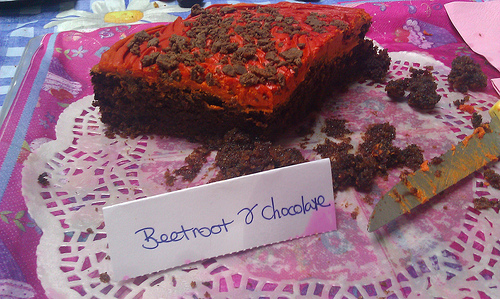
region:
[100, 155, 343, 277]
the sign is white with blue writing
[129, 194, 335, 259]
the sign says beetroot & chocolate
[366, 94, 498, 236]
a knife by the cake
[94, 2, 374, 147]
the cake is brown and red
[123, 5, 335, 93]
chunks of chocolate on the cake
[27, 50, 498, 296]
a white doily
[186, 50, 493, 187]
chunks of cake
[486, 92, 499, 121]
the knife has a yellow handle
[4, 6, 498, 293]
the tray is pink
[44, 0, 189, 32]
a white daisy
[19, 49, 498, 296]
A white doily on a plate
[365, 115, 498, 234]
A knife with orange frosting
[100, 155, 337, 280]
A white sign on the plate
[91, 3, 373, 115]
Orange frosting on a cake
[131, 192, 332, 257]
Words "Beetroot & Chocolate" on a sign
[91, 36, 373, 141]
Chocolate cake on a doily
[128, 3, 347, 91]
Bits of chocolate on frosting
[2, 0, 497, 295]
A pink and blue plate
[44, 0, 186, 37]
A daisy pattern on a tablecloth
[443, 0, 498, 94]
A pink napkin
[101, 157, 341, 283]
white label with blue inkprint on it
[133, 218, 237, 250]
blue ink print reading Beetroot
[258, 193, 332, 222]
blue ink print reading Chocolate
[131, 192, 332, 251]
blue inkprint reading Beetroot and Chocolate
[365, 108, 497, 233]
a sharp silver knife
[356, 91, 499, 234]
knife with orange frosting and cake crumbs on it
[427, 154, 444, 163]
brown cake crumb on a knife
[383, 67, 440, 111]
large chocolate cake crumb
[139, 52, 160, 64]
chocolate topping on a piece of cake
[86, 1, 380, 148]
piece of red frosted chocolate cake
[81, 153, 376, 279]
a handwritten sign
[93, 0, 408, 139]
chocolate cake with red icing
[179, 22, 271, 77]
chocolate shaving on the cake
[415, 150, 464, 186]
crumbs on a knife blade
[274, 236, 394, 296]
oil on a white doily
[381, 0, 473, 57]
colorful table cloth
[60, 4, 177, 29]
a white flower in the tablecloth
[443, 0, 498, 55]
a pink napkin on the table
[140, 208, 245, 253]
blue writing on white paper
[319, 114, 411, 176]
brown crumbs on the doily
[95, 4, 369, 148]
beetroot and chocolate cake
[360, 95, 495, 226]
a knife covered with frosting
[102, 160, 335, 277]
a white paper sign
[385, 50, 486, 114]
pieces of cake on a table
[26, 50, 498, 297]
a white paper doyle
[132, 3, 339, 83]
chocolate bits on icing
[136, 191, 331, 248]
text in blue ink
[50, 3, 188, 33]
flower on a table cloth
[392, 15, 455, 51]
cupcake on a table cloth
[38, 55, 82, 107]
cupcake on a table cloth